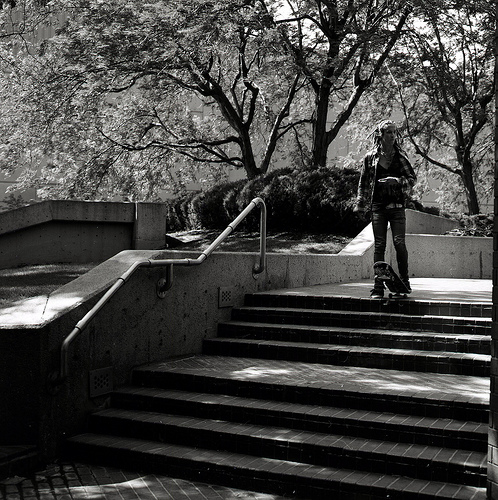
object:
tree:
[387, 0, 497, 215]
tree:
[268, 0, 407, 165]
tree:
[0, 0, 292, 181]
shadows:
[404, 288, 492, 303]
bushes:
[166, 165, 440, 236]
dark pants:
[371, 209, 412, 291]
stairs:
[64, 368, 487, 500]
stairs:
[203, 293, 488, 380]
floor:
[0, 454, 281, 500]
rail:
[60, 197, 268, 378]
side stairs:
[60, 294, 494, 495]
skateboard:
[372, 261, 411, 298]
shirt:
[356, 144, 417, 208]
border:
[243, 294, 492, 317]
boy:
[352, 120, 417, 300]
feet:
[403, 281, 411, 290]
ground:
[0, 276, 491, 500]